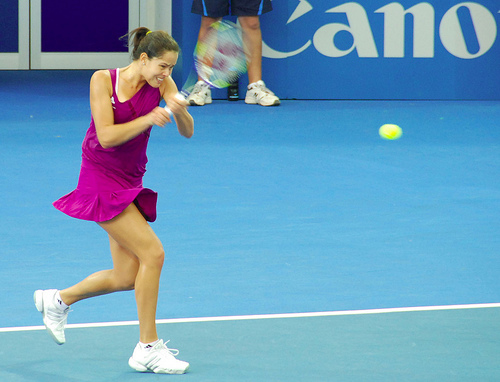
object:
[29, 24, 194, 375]
woman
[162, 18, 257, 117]
racquet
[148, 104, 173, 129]
hands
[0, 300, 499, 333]
line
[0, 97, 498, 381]
court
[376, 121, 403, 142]
ball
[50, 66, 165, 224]
outfit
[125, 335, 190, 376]
shoe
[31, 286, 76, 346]
shoe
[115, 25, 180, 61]
hair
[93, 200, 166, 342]
leg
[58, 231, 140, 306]
leg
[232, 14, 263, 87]
legs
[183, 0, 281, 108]
person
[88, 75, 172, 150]
arm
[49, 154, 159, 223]
skirt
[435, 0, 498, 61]
letters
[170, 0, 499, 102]
wall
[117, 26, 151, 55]
ponytail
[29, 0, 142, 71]
doors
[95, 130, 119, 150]
elbow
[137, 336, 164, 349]
sock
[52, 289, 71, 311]
sock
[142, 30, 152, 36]
band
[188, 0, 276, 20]
shorts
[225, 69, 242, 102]
bottle